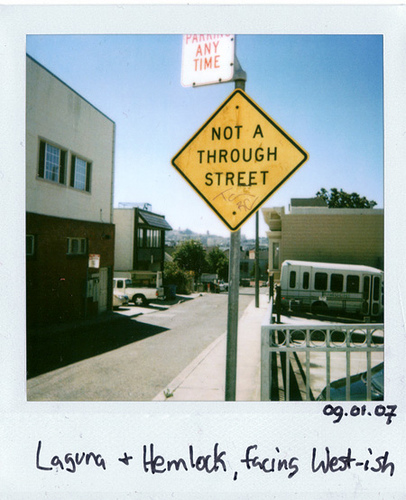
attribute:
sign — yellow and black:
[159, 89, 316, 233]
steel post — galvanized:
[217, 228, 248, 385]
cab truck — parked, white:
[116, 277, 172, 315]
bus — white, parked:
[276, 250, 384, 309]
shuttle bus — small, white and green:
[270, 256, 375, 319]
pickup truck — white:
[119, 273, 180, 315]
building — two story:
[34, 46, 132, 350]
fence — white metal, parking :
[243, 324, 374, 396]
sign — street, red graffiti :
[178, 97, 302, 232]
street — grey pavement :
[140, 318, 176, 365]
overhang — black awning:
[144, 205, 175, 237]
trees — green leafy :
[319, 186, 375, 205]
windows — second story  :
[46, 144, 65, 181]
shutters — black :
[35, 132, 46, 185]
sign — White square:
[180, 33, 230, 82]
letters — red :
[192, 40, 225, 68]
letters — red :
[195, 47, 215, 68]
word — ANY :
[192, 37, 220, 63]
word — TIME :
[195, 37, 219, 73]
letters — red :
[192, 31, 222, 69]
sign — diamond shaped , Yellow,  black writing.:
[171, 89, 306, 235]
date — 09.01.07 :
[321, 397, 393, 419]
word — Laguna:
[29, 439, 119, 480]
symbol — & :
[114, 448, 133, 470]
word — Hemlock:
[142, 441, 225, 474]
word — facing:
[241, 440, 301, 485]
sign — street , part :
[167, 34, 240, 87]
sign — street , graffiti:
[162, 84, 311, 229]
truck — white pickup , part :
[116, 270, 163, 305]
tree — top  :
[297, 185, 389, 212]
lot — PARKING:
[145, 316, 185, 357]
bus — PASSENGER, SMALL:
[284, 257, 382, 310]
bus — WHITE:
[281, 256, 382, 320]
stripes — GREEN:
[283, 288, 308, 304]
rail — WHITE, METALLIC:
[292, 320, 321, 340]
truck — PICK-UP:
[114, 276, 155, 300]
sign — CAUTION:
[166, 97, 306, 223]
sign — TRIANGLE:
[178, 85, 312, 229]